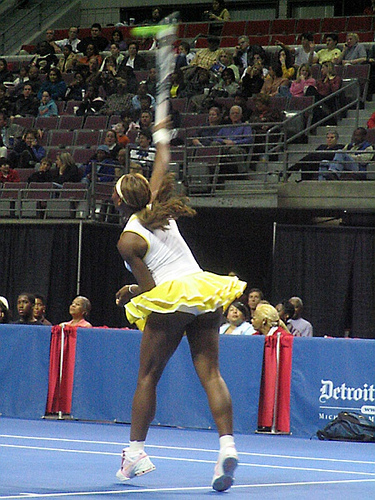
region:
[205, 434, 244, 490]
the woman's right shoe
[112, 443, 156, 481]
the woman's left shoe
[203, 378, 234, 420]
the woman's right calf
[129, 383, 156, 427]
the woman's left calf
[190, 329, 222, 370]
the woman's right thigh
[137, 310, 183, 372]
the woman's left thigh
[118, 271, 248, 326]
the woman is wearing a yellow skirt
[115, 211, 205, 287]
the woman is wearing a white top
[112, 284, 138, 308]
the woman's left hand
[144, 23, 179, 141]
tennis racket the woman is holding in her right hand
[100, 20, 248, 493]
tennis player jumping up to hot ball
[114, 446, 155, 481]
pink and white sneakers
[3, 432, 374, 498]
lines on the tennis court floor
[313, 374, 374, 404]
company endorsers of tennis match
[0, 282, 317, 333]
spectators in the box watching game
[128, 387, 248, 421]
strong calves on tennis player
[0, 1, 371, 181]
people seated high up in the bleechers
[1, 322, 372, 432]
box seperating people and tennis court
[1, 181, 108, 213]
seats at the tennis game stadium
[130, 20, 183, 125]
tennis racket and ball in motion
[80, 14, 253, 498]
Serena serving a tennis ball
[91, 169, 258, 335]
Serena wearing a yellow tennis skirt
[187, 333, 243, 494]
the leg of a woman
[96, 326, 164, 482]
the leg of a woman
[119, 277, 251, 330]
the skirt of a woman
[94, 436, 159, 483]
a white and pink tennis shoe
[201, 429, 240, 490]
a white and pink tennis shoe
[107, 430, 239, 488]
a pair of tennis shoes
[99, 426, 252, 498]
the shoes of a tennis player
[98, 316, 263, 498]
the legs of a woman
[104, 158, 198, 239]
the head of a woman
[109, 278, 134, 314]
the hand of a woman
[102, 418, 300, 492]
the shoes on a woman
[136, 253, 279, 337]
the yellow skirt on a woman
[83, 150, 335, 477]
a woman playing tennis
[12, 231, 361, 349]
people watching a tennis match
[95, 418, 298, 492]
white shoes on a woman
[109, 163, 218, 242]
the hair of a woman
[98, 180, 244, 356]
a woman wearing a white tank top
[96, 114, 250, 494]
tennis player in yellow skort outfit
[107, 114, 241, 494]
tennis player reaching high for a ball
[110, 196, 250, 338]
tennis players yellow skort outfit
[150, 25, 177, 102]
tennis players raquet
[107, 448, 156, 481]
tennis players left tennis shoe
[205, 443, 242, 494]
tennis players right tennis shoe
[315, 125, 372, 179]
audience member watching tennis match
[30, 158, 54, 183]
audience member watching tennis match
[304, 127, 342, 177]
audience member watching tennis match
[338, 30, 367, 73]
audience member watching tennis match